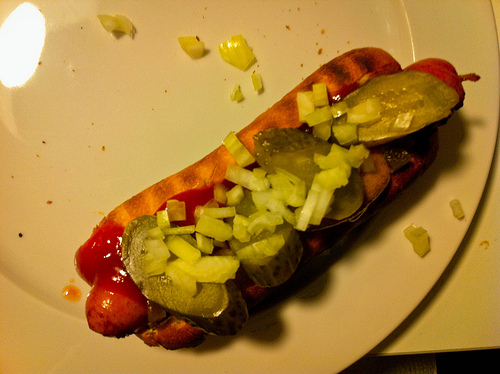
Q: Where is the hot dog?
A: On a white dish.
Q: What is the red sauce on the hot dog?
A: Ketchup.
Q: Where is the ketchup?
A: On the hot dog.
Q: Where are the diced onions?
A: On the hot dog.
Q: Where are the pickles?
A: On the hot dog.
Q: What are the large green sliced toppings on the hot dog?
A: Pickles.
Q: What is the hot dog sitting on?
A: A bun.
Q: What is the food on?
A: White plate.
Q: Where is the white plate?
A: On a table.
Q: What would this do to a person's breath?
A: Make it stink.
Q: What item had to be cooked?
A: The hot dog sausage.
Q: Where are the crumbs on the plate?
A: To the left of the hot dog?.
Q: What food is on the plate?
A: A hot dog.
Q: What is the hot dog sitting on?
A: A round white plate.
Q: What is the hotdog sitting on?
A: A bun on a plate.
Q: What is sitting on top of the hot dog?
A: Toppings.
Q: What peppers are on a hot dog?
A: Jalepeno peppers.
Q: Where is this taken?
A: Table.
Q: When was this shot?
A: Night time.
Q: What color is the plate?
A: White.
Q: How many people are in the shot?
A: 0.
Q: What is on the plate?
A: Hot dog.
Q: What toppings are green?
A: Pickles.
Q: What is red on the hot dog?
A: Ketchup.